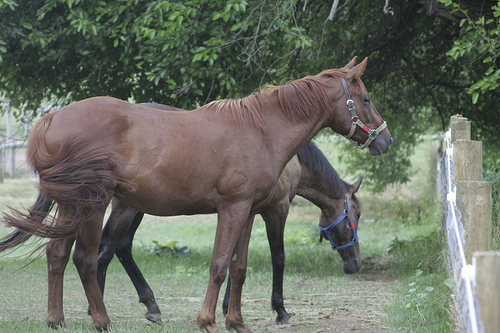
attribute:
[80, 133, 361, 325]
horse — brown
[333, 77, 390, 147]
bridle — tan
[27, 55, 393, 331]
horse — light, brown, light brown, dark brown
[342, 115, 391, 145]
harness — red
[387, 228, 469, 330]
grass — green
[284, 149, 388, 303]
horse — bending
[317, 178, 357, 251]
bridle — blue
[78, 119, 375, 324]
horse — dark brown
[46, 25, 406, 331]
horse — dark brown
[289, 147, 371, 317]
horse — dark brown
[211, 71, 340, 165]
neck — horse's